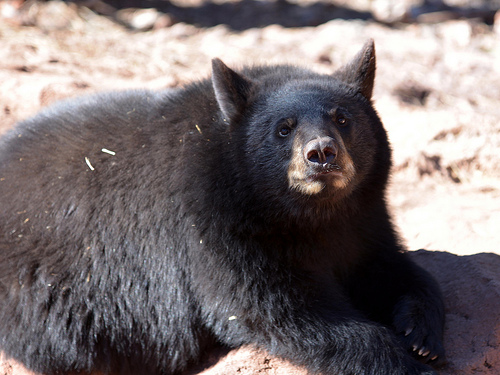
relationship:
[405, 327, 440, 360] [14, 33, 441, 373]
claws of bear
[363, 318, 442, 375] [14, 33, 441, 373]
paw of bear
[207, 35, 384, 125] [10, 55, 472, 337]
ears of bear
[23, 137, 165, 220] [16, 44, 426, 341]
fur of animal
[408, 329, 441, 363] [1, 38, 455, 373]
claws of animal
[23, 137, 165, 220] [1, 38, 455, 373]
fur of animal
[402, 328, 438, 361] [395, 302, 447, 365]
nails on paw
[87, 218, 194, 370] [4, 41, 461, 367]
fur on bear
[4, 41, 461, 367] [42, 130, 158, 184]
bear covered in debris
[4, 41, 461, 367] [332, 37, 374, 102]
bear has ears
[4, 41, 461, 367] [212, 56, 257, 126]
bear has ears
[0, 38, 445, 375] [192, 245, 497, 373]
bear resting on boulder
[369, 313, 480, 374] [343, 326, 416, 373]
paw on top of paw